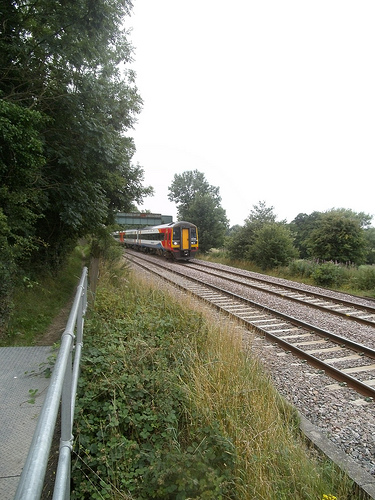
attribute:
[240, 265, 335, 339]
train tracks — parallel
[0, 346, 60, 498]
pavement — small, silver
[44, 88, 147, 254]
leaves — dark green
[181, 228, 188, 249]
door — yellow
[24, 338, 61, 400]
leaves — green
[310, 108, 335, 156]
ground — yellow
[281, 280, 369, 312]
tracks — train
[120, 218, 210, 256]
train — white, blue, red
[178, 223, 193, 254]
door — yellow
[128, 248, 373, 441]
tracks — train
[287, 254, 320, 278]
bush — green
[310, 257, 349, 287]
bush — green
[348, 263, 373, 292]
bush — green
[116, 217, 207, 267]
train — yellow, black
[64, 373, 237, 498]
shrub — overgrown, green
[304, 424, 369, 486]
barrier — concrete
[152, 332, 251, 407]
grass — yellow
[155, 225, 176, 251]
train — red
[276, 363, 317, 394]
gravel — gray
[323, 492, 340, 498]
cluster — small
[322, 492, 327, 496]
flower — yellow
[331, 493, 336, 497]
flower — yellow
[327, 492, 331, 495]
flower — yellow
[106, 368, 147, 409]
clover — green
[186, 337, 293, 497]
weeds — brown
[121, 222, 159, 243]
section — white